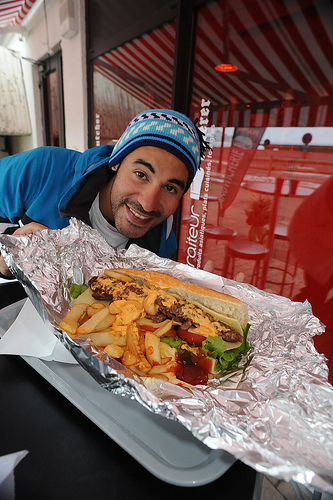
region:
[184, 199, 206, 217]
the white letter R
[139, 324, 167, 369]
this is a fry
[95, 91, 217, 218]
this is a hat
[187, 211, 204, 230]
the white letter U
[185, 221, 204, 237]
the white letter E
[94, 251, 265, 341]
this is a door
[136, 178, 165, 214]
this is a nose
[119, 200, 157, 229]
this is a mouth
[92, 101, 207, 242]
this is a head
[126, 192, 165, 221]
this is a mustache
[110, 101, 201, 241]
The man is wearing a hat.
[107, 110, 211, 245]
The man is wearing a blue hat.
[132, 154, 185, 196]
The man has brown eyes.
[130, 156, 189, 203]
The man has black eyebrows.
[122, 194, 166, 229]
The man has a black mustache.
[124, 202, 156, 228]
The man has white teeth.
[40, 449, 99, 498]
The table is black in color.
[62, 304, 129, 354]
The french fries are golden.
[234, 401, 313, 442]
The foil is silver.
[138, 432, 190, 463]
The food tray is white.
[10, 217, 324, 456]
a sandwich is on aluminum foil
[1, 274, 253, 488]
a gray tray is under the sandwich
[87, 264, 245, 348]
the sandwich has sausage and cheese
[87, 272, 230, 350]
the cheese is melted onto the meat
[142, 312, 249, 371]
tomatoes and spinach are on the sandwich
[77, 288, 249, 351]
slices of cheese surround the meat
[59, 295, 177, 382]
steak fries accompany the hoagie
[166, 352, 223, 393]
a pile of catsup is on the foil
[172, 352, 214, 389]
bar b que sauce is by the gyro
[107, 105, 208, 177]
the man has a knit ski hat on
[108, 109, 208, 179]
blue and white beanie on the man's head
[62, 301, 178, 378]
french fries on the foil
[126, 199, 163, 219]
man has a mustache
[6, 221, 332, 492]
the foil is wrinkled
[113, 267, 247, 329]
white bread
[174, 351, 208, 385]
ketchup for the fries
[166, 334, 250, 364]
green lettuce on the sandwich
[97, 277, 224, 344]
the cheese is on the meat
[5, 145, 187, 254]
man has a blue jacket on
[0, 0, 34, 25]
red and white striped awning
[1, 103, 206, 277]
guy wearing blue clothes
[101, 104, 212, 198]
blue woven winter hat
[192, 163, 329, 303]
reflection of table and bar stools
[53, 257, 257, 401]
cheese burger sandwich with fries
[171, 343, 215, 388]
small pool of red ketchup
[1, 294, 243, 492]
rectangular shiny white plate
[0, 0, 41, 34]
red and white striped awning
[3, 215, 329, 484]
opened crinkled piece of aluminum foil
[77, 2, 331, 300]
reflective glass store front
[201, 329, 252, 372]
crunchy green lettuce leaves